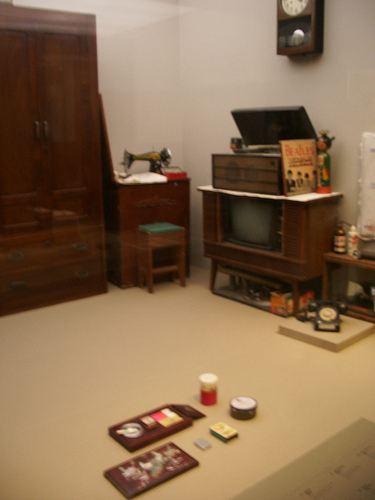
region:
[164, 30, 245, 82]
the wall is white in color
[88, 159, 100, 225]
the cupboard is wooden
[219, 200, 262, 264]
this is a television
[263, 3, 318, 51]
this is a clock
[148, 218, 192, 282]
this is a chair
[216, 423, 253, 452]
this is a matchbox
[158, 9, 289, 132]
this is the wall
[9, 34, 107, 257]
this is a cupboard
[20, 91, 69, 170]
the cupboard is brown in color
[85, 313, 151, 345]
this is the floor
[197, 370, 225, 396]
this is a tin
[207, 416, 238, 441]
this is a match box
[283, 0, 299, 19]
this is a clock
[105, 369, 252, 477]
tools are on the floor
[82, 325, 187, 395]
floor is grey in color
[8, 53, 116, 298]
the cupboard is wooden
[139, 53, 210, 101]
wall is white in color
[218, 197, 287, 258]
tv is on a stand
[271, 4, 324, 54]
clock is on the wall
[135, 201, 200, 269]
stool, is brown in color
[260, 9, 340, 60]
clock holder is brown dark in color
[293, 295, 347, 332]
brown rotary telephone on floor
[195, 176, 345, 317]
brown television case next to wall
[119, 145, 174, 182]
old silver and yellow metal sewing machine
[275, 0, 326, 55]
rectangular brown wooden clock on wall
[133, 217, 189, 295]
brown wooden stool with green seat on top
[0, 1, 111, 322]
large rectangular brown wooden cabinet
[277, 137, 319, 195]
white red and black square album cover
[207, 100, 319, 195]
light brown wooden record player in box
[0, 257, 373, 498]
beige floor with trays and boxes on it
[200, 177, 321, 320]
old TV in a stand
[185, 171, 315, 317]
old television in a stand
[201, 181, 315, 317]
old television inside a stand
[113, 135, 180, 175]
cloth sewing machine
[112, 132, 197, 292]
cloth sewing machine on a stand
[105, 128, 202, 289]
cloth sewing machine on a sewing table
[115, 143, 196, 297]
black cloth sewing machine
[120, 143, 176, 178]
black sewing machine with orange print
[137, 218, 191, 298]
wooden stool on the floor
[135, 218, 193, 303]
wooden stool with a green cushion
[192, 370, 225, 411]
A small red bottle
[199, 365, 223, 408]
The small red bottle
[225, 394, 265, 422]
A circular tube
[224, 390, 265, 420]
The circular tube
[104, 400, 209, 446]
The flat brown object to the left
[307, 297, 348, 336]
dial up black phone on floor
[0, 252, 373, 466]
floor is tan colored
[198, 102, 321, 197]
vintage record player on top of TV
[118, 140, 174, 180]
black and gold sewing machine on dresser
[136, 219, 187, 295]
small wooden chair with green cushion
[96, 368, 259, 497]
pile of blurry objects on floor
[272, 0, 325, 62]
wooden brown wall clock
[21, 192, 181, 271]
reflection on glass window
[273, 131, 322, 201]
beattles record on side of record player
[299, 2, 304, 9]
black number on clock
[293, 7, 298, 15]
black number on clock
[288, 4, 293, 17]
black number on clock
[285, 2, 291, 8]
black number on clock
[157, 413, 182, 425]
item on wooden tray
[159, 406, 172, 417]
item on wooden tray